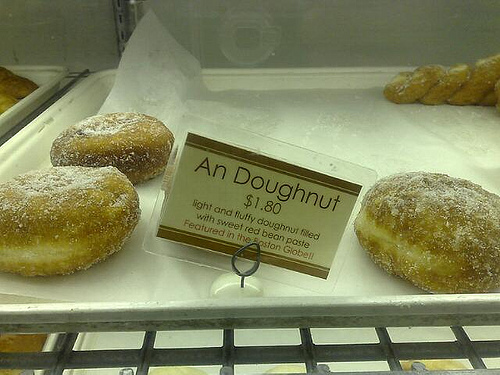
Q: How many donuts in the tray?
A: Four.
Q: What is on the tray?
A: Donuts.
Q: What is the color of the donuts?
A: Brown.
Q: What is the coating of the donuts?
A: Sugar.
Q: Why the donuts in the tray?
A: For sale.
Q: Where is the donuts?
A: In the tray.